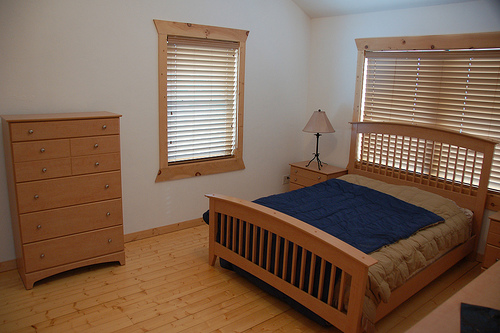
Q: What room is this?
A: Bedroom.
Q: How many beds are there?
A: 1.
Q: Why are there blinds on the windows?
A: To block the sunlight.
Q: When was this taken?
A: During the day.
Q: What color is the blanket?
A: Blue.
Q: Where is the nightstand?
A: Right of the bed.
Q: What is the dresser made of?
A: Wood.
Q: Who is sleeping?
A: No one.